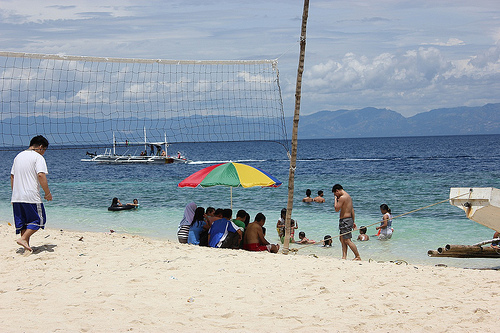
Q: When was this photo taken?
A: During the day.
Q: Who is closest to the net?
A: A man with a white shirt.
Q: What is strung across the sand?
A: A net.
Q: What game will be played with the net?
A: Volleyball.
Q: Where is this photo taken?
A: At the beach.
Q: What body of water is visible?
A: The ocean.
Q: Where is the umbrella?
A: On the sand.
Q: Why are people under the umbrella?
A: For the shade.